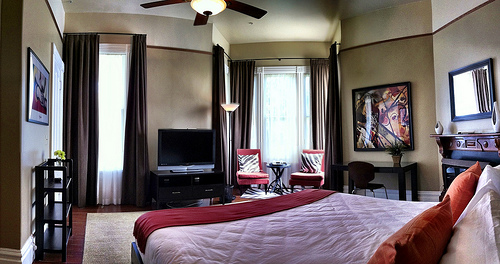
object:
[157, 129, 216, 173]
tv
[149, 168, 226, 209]
table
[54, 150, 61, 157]
flower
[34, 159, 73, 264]
bookstand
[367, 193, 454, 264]
pillow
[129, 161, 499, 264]
bed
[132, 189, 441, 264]
comforter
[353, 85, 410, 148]
painting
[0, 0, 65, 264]
wall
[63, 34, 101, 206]
curtain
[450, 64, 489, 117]
mirror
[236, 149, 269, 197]
chair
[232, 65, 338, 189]
window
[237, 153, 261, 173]
pillow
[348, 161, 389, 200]
chair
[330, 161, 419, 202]
desk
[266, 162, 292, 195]
table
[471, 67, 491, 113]
curtain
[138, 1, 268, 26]
ceiling fan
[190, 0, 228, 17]
light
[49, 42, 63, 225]
door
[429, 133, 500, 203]
fireplace mantel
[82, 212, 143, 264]
rug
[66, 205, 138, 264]
floor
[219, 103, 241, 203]
lamp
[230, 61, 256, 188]
curtains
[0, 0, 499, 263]
room